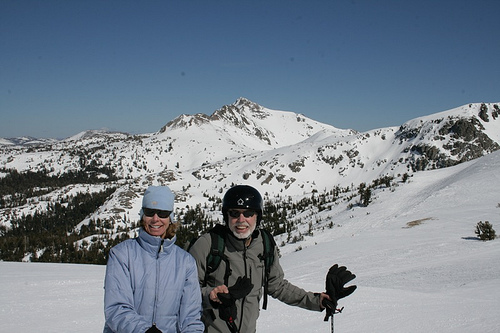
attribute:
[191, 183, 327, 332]
man — smiling, skiing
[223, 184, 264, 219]
helmet — black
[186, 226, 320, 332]
jacket — brown, gray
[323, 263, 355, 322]
glove — black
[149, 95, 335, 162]
mountain — behind, snowy, peak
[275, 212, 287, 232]
tree — behind, evergreen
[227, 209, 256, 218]
glasses — black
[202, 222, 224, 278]
strap — green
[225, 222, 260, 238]
beard — white, gray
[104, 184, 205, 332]
woman — smiling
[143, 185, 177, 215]
hat — blue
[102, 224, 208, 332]
coat — blue